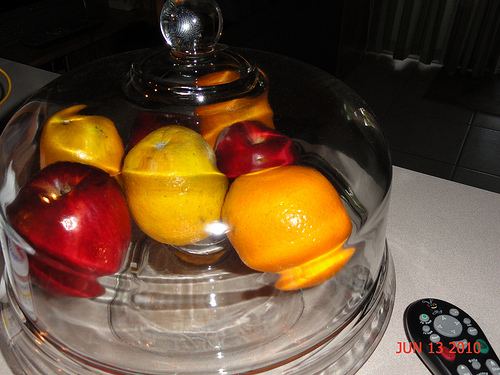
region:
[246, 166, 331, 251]
fruit in a bowl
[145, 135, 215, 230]
fruit in a bowl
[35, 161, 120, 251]
fruit in a bowl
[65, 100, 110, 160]
fruit in a bowl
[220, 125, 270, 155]
fruit in a bowl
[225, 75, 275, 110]
fruit in a bowl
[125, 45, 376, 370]
large bowl of fruit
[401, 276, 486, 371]
remote on a table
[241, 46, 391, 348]
bowl on a table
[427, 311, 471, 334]
button on a remote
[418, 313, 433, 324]
grey button on remote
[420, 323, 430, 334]
grey button on remote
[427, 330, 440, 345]
grey button on remote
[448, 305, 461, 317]
grey button on remote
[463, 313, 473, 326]
grey button on remote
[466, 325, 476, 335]
grey button on remote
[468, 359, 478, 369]
grey button on remote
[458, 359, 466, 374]
grey button on remote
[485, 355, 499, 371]
grey button on remote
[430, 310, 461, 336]
grey button on remote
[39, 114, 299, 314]
a bowl of furit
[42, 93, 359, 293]
a bowl of apples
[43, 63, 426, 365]
a bowl of red apples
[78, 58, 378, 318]
a bowl of oranges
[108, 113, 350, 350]
a bowl of oranges and apples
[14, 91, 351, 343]
bowl of oranges and red apples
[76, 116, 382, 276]
apples that are covered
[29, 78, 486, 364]
red apples that are covered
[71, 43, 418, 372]
oranges that are covered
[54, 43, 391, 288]
fruit on a table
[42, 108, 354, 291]
three oranges in a row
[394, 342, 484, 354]
the date in red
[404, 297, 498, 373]
a black remote control with gray buttons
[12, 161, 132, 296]
a red apple under glass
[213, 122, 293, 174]
a red apple between two oranges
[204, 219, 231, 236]
the light reflecting off of glass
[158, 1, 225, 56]
the round glass top of a glass lid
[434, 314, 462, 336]
a four direction gray button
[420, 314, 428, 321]
a small green button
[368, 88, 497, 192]
tile floor behind the counter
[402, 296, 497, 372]
Tv remote sitting on the table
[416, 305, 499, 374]
Gray buttons on black remote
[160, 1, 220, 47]
Round glass knob on glass dome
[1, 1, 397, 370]
Round glass dome on top of fruit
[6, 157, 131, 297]
Red apple under glass dome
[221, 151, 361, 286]
Orange under glass dome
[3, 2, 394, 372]
Glass dome sitting on top of table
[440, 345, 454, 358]
Red button on remote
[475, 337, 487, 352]
Green button on remote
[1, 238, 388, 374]
Gold stripe on bottom of glass dome